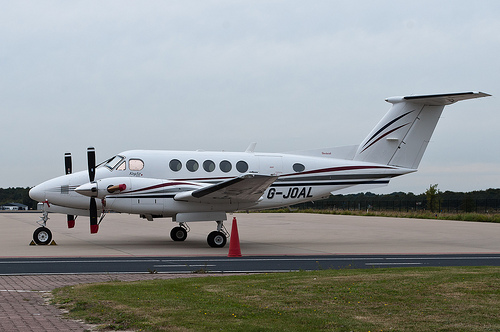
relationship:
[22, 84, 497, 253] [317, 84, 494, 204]
plane has tail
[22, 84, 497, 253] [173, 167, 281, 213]
plane has wing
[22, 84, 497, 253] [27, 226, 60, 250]
plane has wheel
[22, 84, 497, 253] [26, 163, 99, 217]
plane has nose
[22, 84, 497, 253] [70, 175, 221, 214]
plane has engine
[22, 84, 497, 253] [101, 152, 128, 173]
plane has windshield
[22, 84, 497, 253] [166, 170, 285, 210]
plane has left wing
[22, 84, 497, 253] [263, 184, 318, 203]
plane has name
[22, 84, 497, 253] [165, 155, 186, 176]
plane has window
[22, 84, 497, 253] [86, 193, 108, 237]
plane has propeller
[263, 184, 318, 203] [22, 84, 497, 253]
name written on plane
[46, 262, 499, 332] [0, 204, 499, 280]
grass near runway